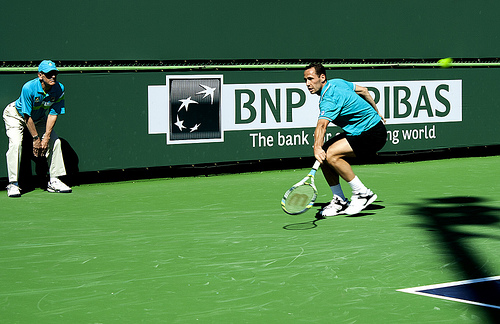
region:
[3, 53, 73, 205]
man in blue hat standing against the wall on court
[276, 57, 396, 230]
man holding tennis racket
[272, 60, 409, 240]
man in black shorts playing tennis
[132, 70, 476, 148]
sign on wall of tennis court in bold letters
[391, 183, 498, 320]
shadow on tennis court behind player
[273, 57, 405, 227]
tennis player in blue shirt leaning forward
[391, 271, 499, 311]
white lines outlining blue tennis court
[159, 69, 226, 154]
bank symbol on left side of sign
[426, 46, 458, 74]
green tennis ball flying through the air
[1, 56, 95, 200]
man with black shades watching tennis match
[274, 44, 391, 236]
The man is holding a tennis racket.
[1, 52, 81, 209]
The man is leaning against the barrier wall.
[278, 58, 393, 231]
The man's knees are bent.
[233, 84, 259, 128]
The letter is green.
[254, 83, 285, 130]
The letter is green.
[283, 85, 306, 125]
The letter is green.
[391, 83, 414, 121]
The letter is green.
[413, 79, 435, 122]
The letter is green.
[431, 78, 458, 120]
The letter is green.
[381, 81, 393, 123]
The letter is green.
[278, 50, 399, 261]
man on a tennis court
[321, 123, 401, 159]
man wearing black shorts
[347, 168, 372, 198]
man wearing white socks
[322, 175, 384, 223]
man wearing white and black sneakers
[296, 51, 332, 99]
man with black hair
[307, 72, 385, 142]
man wearing a blue shirt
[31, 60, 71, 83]
man wearing a hat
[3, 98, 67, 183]
man wearing tan pants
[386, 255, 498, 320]
white lines on a court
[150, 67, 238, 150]
logo on the wall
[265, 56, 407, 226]
Man is in the foreground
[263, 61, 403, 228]
Man is playing tennis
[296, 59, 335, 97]
Man has short dark hair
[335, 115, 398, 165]
The shorts are black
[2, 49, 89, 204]
A man on the left side of the image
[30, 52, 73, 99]
Man is wearing a cap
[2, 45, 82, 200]
Man is bent over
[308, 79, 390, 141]
Man is wearing a light blue shirt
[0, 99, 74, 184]
Man is wearing tan colored pants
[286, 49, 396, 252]
this is a person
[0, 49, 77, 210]
this is a person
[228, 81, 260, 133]
a letter on the banner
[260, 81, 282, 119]
a letter on the banner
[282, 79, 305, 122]
a letter on the banner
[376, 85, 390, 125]
a letter on the banner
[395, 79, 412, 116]
a letter on the banner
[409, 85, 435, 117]
a letter on the banner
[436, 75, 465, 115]
a letter on the banner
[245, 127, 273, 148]
a letter on the banner